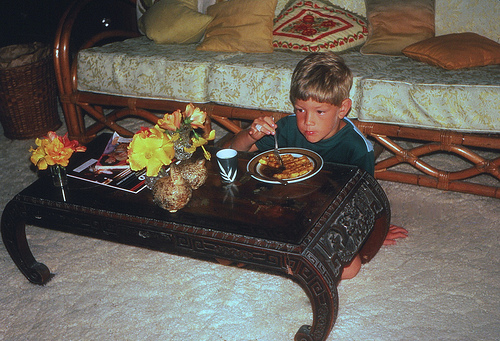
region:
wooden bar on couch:
[447, 142, 474, 164]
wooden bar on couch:
[414, 158, 442, 176]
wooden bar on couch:
[447, 162, 479, 181]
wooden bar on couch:
[406, 143, 438, 162]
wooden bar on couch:
[368, 133, 400, 156]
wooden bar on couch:
[375, 150, 400, 172]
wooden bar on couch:
[205, 113, 233, 133]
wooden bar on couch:
[108, 110, 128, 124]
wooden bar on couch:
[80, 103, 99, 118]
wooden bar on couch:
[83, 118, 103, 135]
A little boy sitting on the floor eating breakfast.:
[218, 54, 409, 281]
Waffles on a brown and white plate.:
[245, 144, 323, 186]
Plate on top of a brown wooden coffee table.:
[0, 131, 389, 340]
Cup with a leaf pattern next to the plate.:
[214, 147, 238, 187]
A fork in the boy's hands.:
[247, 113, 284, 170]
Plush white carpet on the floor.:
[0, 101, 499, 340]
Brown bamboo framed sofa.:
[52, 1, 499, 203]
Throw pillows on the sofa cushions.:
[141, 0, 498, 70]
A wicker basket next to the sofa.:
[1, 43, 61, 139]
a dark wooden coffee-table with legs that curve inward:
[1, 131, 389, 337]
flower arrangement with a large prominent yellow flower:
[126, 101, 213, 209]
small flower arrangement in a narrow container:
[26, 129, 86, 189]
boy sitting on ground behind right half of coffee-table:
[215, 50, 408, 338]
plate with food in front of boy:
[221, 51, 371, 186]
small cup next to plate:
[215, 146, 323, 185]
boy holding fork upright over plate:
[246, 113, 324, 183]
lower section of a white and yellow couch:
[54, 1, 499, 200]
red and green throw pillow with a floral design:
[271, 0, 368, 55]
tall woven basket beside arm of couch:
[0, 0, 134, 140]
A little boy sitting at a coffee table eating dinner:
[224, 51, 408, 288]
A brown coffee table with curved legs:
[1, 140, 395, 340]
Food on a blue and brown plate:
[245, 146, 325, 186]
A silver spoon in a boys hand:
[271, 125, 281, 160]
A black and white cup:
[215, 145, 236, 182]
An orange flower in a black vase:
[29, 128, 87, 203]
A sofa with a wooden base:
[59, 14, 499, 204]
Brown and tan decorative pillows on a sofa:
[138, 0, 493, 70]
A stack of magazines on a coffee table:
[63, 133, 155, 193]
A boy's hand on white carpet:
[382, 226, 412, 242]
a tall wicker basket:
[0, 38, 66, 138]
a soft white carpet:
[408, 213, 489, 325]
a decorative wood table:
[10, 126, 395, 334]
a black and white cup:
[214, 147, 241, 185]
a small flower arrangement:
[23, 128, 91, 182]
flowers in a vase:
[153, 104, 215, 157]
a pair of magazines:
[71, 119, 158, 196]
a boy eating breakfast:
[218, 58, 413, 274]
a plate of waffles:
[253, 143, 330, 183]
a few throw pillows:
[126, 0, 492, 75]